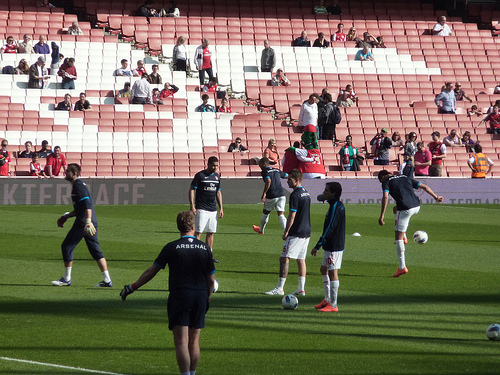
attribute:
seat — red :
[403, 59, 418, 68]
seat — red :
[424, 58, 438, 67]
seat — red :
[399, 52, 411, 57]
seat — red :
[426, 57, 440, 67]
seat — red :
[425, 52, 437, 59]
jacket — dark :
[258, 46, 277, 68]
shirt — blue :
[147, 232, 223, 294]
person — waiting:
[467, 141, 495, 180]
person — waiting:
[427, 130, 448, 175]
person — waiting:
[412, 139, 434, 176]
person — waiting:
[402, 134, 416, 162]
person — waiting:
[389, 130, 403, 148]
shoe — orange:
[314, 295, 330, 310]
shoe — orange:
[317, 302, 337, 313]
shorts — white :
[267, 223, 320, 287]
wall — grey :
[1, 172, 498, 217]